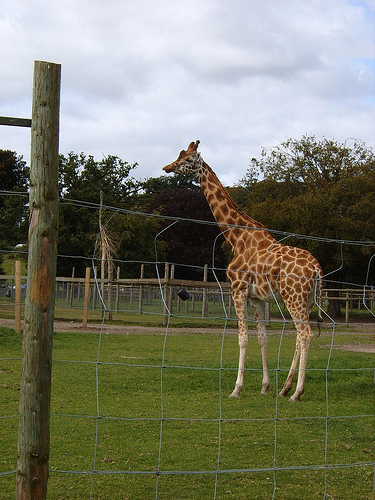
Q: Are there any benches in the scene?
A: No, there are no benches.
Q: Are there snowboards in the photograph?
A: No, there are no snowboards.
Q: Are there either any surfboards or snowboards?
A: No, there are no snowboards or surfboards.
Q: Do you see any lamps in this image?
A: No, there are no lamps.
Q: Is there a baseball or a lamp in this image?
A: No, there are no lamps or baseballs.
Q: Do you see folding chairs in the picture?
A: No, there are no folding chairs.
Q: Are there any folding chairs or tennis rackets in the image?
A: No, there are no folding chairs or tennis rackets.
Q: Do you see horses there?
A: No, there are no horses.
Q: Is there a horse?
A: No, there are no horses.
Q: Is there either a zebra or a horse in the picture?
A: No, there are no horses or zebras.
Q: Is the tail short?
A: Yes, the tail is short.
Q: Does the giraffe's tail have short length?
A: Yes, the tail is short.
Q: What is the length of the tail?
A: The tail is short.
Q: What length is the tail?
A: The tail is short.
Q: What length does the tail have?
A: The tail has short length.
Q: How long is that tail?
A: The tail is short.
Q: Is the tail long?
A: No, the tail is short.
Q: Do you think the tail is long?
A: No, the tail is short.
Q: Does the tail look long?
A: No, the tail is short.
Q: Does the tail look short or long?
A: The tail is short.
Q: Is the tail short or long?
A: The tail is short.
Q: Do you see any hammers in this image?
A: No, there are no hammers.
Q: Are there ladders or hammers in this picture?
A: No, there are no hammers or ladders.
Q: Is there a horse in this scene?
A: No, there are no horses.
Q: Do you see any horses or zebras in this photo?
A: No, there are no horses or zebras.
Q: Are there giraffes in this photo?
A: Yes, there is a giraffe.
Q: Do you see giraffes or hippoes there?
A: Yes, there is a giraffe.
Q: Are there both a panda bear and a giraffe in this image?
A: No, there is a giraffe but no panda bears.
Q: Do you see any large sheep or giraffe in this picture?
A: Yes, there is a large giraffe.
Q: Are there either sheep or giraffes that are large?
A: Yes, the giraffe is large.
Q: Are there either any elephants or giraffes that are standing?
A: Yes, the giraffe is standing.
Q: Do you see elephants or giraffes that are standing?
A: Yes, the giraffe is standing.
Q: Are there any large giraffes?
A: Yes, there is a large giraffe.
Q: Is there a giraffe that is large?
A: Yes, there is a giraffe that is large.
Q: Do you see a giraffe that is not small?
A: Yes, there is a large giraffe.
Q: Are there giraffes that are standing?
A: Yes, there is a giraffe that is standing.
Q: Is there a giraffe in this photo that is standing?
A: Yes, there is a giraffe that is standing.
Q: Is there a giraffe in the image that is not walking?
A: Yes, there is a giraffe that is standing.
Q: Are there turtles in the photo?
A: No, there are no turtles.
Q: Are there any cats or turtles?
A: No, there are no turtles or cats.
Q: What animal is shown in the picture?
A: The animal is a giraffe.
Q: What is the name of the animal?
A: The animal is a giraffe.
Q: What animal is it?
A: The animal is a giraffe.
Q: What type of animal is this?
A: This is a giraffe.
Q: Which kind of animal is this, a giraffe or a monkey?
A: This is a giraffe.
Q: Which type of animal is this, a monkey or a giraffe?
A: This is a giraffe.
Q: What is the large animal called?
A: The animal is a giraffe.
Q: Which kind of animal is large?
A: The animal is a giraffe.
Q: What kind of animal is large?
A: The animal is a giraffe.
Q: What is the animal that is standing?
A: The animal is a giraffe.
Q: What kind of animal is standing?
A: The animal is a giraffe.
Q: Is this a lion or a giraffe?
A: This is a giraffe.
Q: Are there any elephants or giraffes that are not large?
A: No, there is a giraffe but it is large.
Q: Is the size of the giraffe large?
A: Yes, the giraffe is large.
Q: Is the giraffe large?
A: Yes, the giraffe is large.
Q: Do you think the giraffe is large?
A: Yes, the giraffe is large.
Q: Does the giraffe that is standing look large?
A: Yes, the giraffe is large.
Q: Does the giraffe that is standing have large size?
A: Yes, the giraffe is large.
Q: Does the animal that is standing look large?
A: Yes, the giraffe is large.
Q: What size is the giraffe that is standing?
A: The giraffe is large.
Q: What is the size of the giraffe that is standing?
A: The giraffe is large.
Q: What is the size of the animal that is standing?
A: The giraffe is large.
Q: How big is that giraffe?
A: The giraffe is large.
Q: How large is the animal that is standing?
A: The giraffe is large.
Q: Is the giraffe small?
A: No, the giraffe is large.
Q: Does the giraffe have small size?
A: No, the giraffe is large.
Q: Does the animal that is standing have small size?
A: No, the giraffe is large.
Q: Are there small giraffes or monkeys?
A: No, there is a giraffe but it is large.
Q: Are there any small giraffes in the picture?
A: No, there is a giraffe but it is large.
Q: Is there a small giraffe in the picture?
A: No, there is a giraffe but it is large.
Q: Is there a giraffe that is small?
A: No, there is a giraffe but it is large.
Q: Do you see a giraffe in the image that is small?
A: No, there is a giraffe but it is large.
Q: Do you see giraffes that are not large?
A: No, there is a giraffe but it is large.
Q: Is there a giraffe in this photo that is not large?
A: No, there is a giraffe but it is large.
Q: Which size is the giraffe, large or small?
A: The giraffe is large.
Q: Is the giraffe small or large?
A: The giraffe is large.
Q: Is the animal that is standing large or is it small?
A: The giraffe is large.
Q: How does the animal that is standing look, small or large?
A: The giraffe is large.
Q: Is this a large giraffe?
A: Yes, this is a large giraffe.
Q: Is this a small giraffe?
A: No, this is a large giraffe.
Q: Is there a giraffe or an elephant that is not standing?
A: No, there is a giraffe but it is standing.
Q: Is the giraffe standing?
A: Yes, the giraffe is standing.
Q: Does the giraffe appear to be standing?
A: Yes, the giraffe is standing.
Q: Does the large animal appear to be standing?
A: Yes, the giraffe is standing.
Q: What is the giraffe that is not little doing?
A: The giraffe is standing.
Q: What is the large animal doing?
A: The giraffe is standing.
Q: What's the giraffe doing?
A: The giraffe is standing.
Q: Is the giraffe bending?
A: No, the giraffe is standing.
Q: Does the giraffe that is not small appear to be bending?
A: No, the giraffe is standing.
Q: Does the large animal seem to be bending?
A: No, the giraffe is standing.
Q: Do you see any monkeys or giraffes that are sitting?
A: No, there is a giraffe but it is standing.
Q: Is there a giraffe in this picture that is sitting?
A: No, there is a giraffe but it is standing.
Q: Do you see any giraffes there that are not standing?
A: No, there is a giraffe but it is standing.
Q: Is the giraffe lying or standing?
A: The giraffe is standing.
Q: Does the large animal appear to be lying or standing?
A: The giraffe is standing.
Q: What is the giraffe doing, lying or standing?
A: The giraffe is standing.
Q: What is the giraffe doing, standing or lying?
A: The giraffe is standing.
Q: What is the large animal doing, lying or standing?
A: The giraffe is standing.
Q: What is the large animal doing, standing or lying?
A: The giraffe is standing.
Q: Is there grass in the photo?
A: Yes, there is grass.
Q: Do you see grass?
A: Yes, there is grass.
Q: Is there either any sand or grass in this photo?
A: Yes, there is grass.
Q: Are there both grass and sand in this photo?
A: No, there is grass but no sand.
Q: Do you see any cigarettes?
A: No, there are no cigarettes.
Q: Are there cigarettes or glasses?
A: No, there are no cigarettes or glasses.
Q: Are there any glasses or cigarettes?
A: No, there are no cigarettes or glasses.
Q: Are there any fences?
A: Yes, there is a fence.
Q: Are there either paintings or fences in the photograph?
A: Yes, there is a fence.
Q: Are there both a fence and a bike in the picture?
A: No, there is a fence but no bikes.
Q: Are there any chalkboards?
A: No, there are no chalkboards.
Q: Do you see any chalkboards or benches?
A: No, there are no chalkboards or benches.